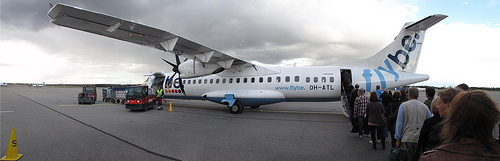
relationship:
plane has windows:
[48, 0, 448, 112] [177, 75, 340, 86]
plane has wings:
[48, 0, 448, 112] [39, 2, 271, 70]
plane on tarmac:
[48, 0, 448, 112] [4, 86, 500, 161]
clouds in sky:
[39, 2, 271, 70] [2, 0, 500, 91]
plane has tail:
[48, 0, 448, 112] [357, 11, 450, 103]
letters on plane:
[357, 11, 450, 103] [48, 0, 448, 112]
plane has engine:
[48, 0, 448, 112] [159, 49, 220, 82]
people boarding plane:
[342, 70, 500, 161] [48, 0, 448, 112]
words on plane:
[363, 23, 420, 93] [48, 0, 448, 112]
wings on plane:
[39, 2, 271, 70] [48, 0, 448, 112]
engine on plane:
[159, 49, 220, 82] [48, 0, 448, 112]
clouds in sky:
[1, 6, 315, 64] [2, 0, 500, 91]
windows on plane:
[177, 75, 340, 86] [48, 0, 448, 112]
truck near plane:
[123, 79, 167, 116] [48, 0, 448, 112]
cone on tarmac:
[3, 124, 29, 159] [4, 86, 500, 161]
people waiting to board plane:
[342, 70, 500, 161] [48, 0, 448, 112]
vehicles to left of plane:
[76, 82, 158, 112] [48, 0, 448, 112]